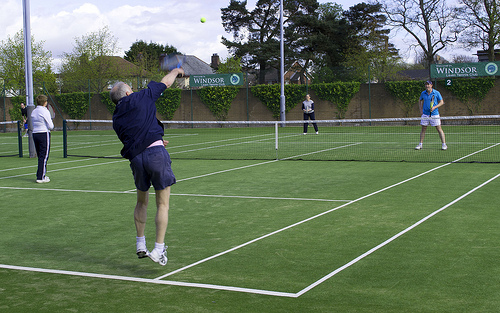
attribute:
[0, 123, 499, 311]
court — green, tennis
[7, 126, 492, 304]
lines — white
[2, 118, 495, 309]
field — green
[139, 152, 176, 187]
short — black, woman's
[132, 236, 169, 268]
sneakers — white, blue, pair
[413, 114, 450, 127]
shorts — man's, white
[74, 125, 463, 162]
net — black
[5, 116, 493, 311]
grass — very short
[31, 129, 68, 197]
pants — stripes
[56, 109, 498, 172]
net — tennis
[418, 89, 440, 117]
shirt — bleu, short sleeve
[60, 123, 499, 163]
tennis net — long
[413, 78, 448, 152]
man — standing, standing in wide leg stance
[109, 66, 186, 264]
man — swinging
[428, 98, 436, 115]
racket — tennis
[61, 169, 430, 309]
lines — white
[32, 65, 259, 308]
tennis player — jumping in air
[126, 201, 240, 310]
shoes — tennis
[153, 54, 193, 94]
hand — person's